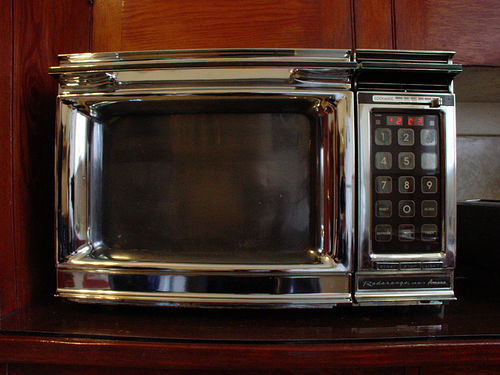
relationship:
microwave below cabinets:
[46, 43, 466, 325] [89, 0, 493, 45]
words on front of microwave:
[362, 274, 453, 290] [46, 43, 466, 325]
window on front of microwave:
[94, 112, 311, 250] [46, 43, 466, 325]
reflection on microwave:
[62, 107, 108, 174] [46, 43, 466, 325]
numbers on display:
[392, 111, 427, 130] [369, 109, 443, 130]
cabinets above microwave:
[89, 0, 493, 45] [46, 43, 466, 325]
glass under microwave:
[7, 272, 494, 336] [46, 43, 466, 325]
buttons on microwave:
[371, 260, 450, 279] [46, 43, 466, 325]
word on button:
[420, 203, 438, 214] [414, 193, 442, 222]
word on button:
[420, 203, 438, 214] [372, 221, 391, 245]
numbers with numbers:
[392, 111, 427, 130] [392, 111, 427, 130]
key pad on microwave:
[366, 125, 439, 234] [46, 43, 466, 325]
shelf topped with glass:
[0, 342, 488, 373] [10, 298, 492, 332]